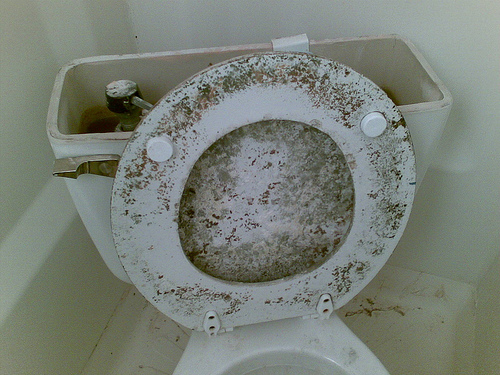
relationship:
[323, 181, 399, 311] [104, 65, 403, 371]
dots on seat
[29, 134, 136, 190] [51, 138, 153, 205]
spots on lever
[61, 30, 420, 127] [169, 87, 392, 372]
tank opening behind toilet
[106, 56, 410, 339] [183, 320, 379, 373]
seat on toilet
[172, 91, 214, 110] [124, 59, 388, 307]
stains on seat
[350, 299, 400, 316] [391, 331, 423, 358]
stains on floor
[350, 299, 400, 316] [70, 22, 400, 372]
stains near toilet